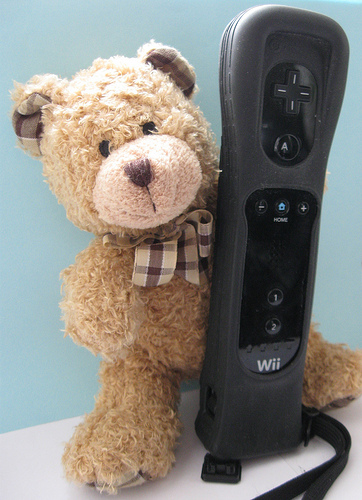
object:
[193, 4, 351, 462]
wii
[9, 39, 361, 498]
bear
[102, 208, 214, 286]
scarf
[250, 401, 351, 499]
strap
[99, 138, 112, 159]
eye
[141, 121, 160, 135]
eye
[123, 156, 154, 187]
nose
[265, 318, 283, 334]
button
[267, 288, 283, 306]
button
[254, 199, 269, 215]
button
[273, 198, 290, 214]
button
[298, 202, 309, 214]
button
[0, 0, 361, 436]
background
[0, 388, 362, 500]
object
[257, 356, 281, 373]
lettering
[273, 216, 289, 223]
lettering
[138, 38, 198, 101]
ear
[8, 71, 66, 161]
ear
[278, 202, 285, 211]
icon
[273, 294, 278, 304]
number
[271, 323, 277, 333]
number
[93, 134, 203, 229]
snout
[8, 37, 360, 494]
fur